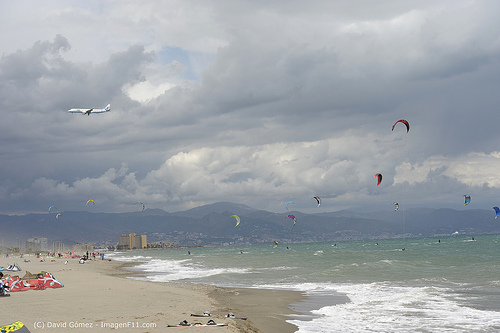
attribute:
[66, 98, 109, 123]
plane — white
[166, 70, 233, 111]
sky — cloudy, gray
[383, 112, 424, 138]
kite — red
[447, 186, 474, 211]
kite — blue